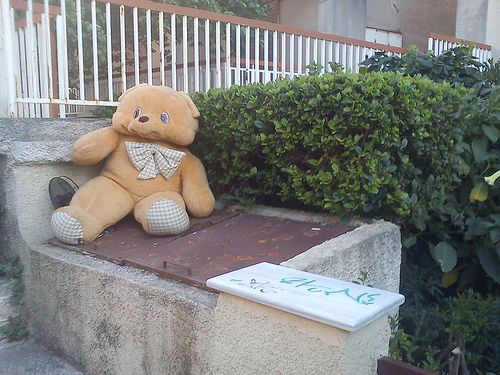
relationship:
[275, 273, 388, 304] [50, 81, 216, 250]
grafitti by bear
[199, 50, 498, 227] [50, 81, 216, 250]
shrubs behind bear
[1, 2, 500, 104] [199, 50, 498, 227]
railing near shrubs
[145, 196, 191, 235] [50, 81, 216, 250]
foot of bear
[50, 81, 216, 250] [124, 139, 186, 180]
bear has a bow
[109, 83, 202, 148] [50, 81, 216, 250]
head of bear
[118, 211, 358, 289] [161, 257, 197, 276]
door has a handle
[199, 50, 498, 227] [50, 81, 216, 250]
bush behind bear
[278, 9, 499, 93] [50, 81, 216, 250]
building behind bear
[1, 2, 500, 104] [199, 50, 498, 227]
railing by shrubs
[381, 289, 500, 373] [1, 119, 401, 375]
plant by wall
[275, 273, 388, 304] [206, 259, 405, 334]
grafitti on tile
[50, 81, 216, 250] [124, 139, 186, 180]
bear with a bow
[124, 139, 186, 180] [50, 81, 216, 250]
bow on bear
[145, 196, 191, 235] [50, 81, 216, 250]
foot on a bear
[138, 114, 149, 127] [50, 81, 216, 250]
nose on bear